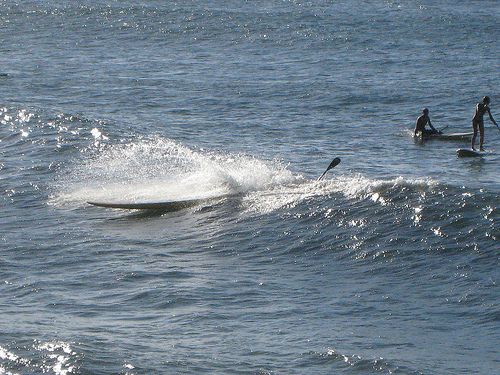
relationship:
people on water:
[416, 92, 498, 156] [1, 0, 496, 373]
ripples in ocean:
[28, 212, 404, 359] [0, 3, 499, 372]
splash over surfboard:
[57, 121, 264, 179] [85, 190, 223, 212]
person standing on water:
[469, 92, 498, 154] [340, 159, 497, 279]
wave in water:
[34, 122, 499, 239] [1, 0, 496, 373]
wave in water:
[150, 117, 408, 232] [1, 0, 496, 373]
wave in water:
[25, 328, 128, 373] [1, 0, 496, 373]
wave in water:
[125, 157, 368, 224] [1, 0, 496, 373]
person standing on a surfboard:
[469, 92, 498, 154] [457, 143, 480, 160]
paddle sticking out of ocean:
[316, 155, 342, 182] [0, 3, 499, 372]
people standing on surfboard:
[416, 92, 498, 156] [455, 145, 484, 160]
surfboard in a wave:
[85, 187, 256, 208] [30, 117, 491, 259]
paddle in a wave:
[316, 155, 342, 182] [30, 117, 491, 259]